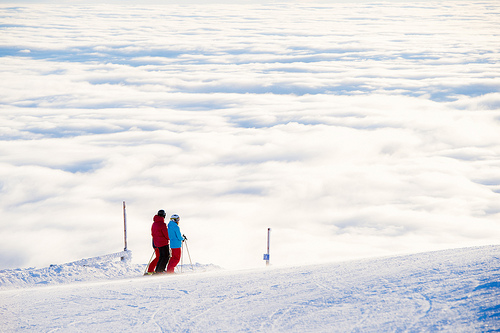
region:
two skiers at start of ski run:
[137, 186, 196, 278]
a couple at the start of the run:
[135, 200, 195, 285]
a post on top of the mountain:
[100, 190, 144, 258]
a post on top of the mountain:
[237, 222, 282, 277]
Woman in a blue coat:
[164, 208, 193, 280]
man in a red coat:
[142, 202, 170, 286]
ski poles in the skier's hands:
[177, 236, 191, 270]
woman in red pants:
[164, 205, 190, 284]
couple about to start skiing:
[140, 202, 198, 288]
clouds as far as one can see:
[12, 16, 493, 217]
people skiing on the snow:
[133, 202, 212, 278]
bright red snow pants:
[165, 247, 185, 273]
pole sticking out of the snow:
[259, 218, 276, 264]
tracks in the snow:
[404, 285, 443, 332]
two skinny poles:
[114, 194, 290, 265]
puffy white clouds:
[0, 9, 483, 259]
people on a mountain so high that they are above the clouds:
[2, 4, 487, 323]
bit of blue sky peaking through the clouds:
[7, 41, 71, 60]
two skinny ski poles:
[175, 240, 204, 272]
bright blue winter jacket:
[166, 219, 185, 246]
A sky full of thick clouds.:
[1, 4, 492, 211]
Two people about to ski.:
[134, 203, 199, 285]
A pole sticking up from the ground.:
[110, 196, 137, 272]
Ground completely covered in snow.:
[68, 261, 496, 328]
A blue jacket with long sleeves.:
[165, 221, 187, 245]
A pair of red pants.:
[166, 248, 183, 276]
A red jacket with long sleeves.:
[148, 216, 171, 253]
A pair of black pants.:
[154, 249, 174, 277]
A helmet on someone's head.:
[167, 213, 184, 225]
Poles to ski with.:
[176, 237, 199, 277]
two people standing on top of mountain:
[135, 199, 192, 287]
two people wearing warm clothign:
[137, 200, 197, 285]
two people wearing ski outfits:
[140, 201, 195, 287]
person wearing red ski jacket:
[140, 206, 168, 276]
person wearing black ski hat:
[143, 206, 175, 279]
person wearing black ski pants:
[137, 210, 172, 281]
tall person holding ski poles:
[137, 204, 172, 274]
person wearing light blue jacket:
[166, 211, 189, 277]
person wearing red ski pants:
[166, 209, 188, 276]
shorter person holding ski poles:
[164, 213, 196, 273]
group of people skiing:
[133, 201, 210, 283]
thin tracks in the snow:
[339, 290, 430, 331]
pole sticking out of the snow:
[252, 221, 284, 261]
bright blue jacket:
[164, 221, 189, 248]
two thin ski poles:
[175, 238, 200, 274]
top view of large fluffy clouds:
[3, 5, 497, 260]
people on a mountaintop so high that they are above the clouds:
[0, 10, 482, 331]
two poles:
[114, 196, 301, 273]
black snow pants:
[147, 242, 171, 273]